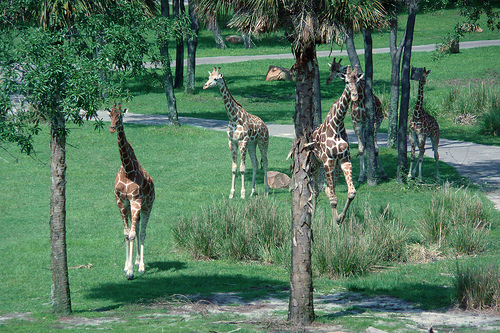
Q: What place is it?
A: It is a park.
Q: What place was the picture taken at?
A: It was taken at the park.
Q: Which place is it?
A: It is a park.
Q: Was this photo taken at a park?
A: Yes, it was taken in a park.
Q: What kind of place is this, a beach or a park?
A: It is a park.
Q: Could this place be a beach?
A: No, it is a park.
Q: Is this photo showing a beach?
A: No, the picture is showing a park.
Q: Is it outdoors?
A: Yes, it is outdoors.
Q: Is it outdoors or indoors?
A: It is outdoors.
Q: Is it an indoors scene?
A: No, it is outdoors.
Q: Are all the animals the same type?
A: Yes, all the animals are giraffes.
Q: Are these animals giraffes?
A: Yes, all the animals are giraffes.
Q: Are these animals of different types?
A: No, all the animals are giraffes.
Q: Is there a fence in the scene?
A: No, there are no fences.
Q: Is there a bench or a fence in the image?
A: No, there are no fences or benches.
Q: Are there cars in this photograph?
A: No, there are no cars.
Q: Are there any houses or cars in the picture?
A: No, there are no cars or houses.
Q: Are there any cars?
A: No, there are no cars.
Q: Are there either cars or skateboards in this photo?
A: No, there are no cars or skateboards.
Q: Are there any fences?
A: No, there are no fences.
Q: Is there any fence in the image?
A: No, there are no fences.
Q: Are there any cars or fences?
A: No, there are no fences or cars.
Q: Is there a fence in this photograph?
A: No, there are no fences.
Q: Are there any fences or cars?
A: No, there are no fences or cars.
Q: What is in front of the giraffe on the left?
A: The tree is in front of the giraffe.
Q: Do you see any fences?
A: No, there are no fences.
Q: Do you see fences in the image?
A: No, there are no fences.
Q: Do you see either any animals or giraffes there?
A: Yes, there is a giraffe.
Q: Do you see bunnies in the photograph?
A: No, there are no bunnies.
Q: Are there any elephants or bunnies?
A: No, there are no bunnies or elephants.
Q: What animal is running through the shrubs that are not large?
A: The giraffe is running through the shrubs.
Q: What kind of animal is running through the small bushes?
A: The animal is a giraffe.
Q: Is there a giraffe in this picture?
A: Yes, there is a giraffe.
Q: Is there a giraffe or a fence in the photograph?
A: Yes, there is a giraffe.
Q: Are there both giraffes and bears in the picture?
A: No, there is a giraffe but no bears.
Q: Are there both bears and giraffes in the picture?
A: No, there is a giraffe but no bears.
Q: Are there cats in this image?
A: No, there are no cats.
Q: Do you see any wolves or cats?
A: No, there are no cats or wolves.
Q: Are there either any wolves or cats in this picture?
A: No, there are no cats or wolves.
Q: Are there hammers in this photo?
A: No, there are no hammers.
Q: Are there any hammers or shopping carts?
A: No, there are no hammers or shopping carts.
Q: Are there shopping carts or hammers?
A: No, there are no hammers or shopping carts.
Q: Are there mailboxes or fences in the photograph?
A: No, there are no fences or mailboxes.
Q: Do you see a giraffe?
A: Yes, there is a giraffe.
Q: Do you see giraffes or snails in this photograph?
A: Yes, there is a giraffe.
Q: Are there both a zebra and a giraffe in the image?
A: No, there is a giraffe but no zebras.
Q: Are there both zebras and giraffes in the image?
A: No, there is a giraffe but no zebras.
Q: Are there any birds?
A: No, there are no birds.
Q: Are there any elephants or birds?
A: No, there are no birds or elephants.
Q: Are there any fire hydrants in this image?
A: No, there are no fire hydrants.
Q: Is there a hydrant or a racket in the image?
A: No, there are no fire hydrants or rackets.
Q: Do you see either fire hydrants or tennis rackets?
A: No, there are no fire hydrants or tennis rackets.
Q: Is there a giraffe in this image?
A: Yes, there is a giraffe.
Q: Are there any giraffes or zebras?
A: Yes, there is a giraffe.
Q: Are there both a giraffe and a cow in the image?
A: No, there is a giraffe but no cows.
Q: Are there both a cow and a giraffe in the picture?
A: No, there is a giraffe but no cows.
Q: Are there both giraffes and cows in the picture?
A: No, there is a giraffe but no cows.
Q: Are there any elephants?
A: No, there are no elephants.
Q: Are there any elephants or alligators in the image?
A: No, there are no elephants or alligators.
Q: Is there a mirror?
A: No, there are no mirrors.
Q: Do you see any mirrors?
A: No, there are no mirrors.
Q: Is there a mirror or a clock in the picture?
A: No, there are no mirrors or clocks.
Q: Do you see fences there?
A: No, there are no fences.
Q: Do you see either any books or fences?
A: No, there are no fences or books.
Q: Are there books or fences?
A: No, there are no fences or books.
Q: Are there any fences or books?
A: No, there are no fences or books.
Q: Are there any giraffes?
A: Yes, there is a giraffe.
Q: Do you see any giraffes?
A: Yes, there is a giraffe.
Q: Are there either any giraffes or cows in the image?
A: Yes, there is a giraffe.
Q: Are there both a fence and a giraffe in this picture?
A: No, there is a giraffe but no fences.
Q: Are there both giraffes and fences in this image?
A: No, there is a giraffe but no fences.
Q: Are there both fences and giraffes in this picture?
A: No, there is a giraffe but no fences.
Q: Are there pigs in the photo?
A: No, there are no pigs.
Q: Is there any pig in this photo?
A: No, there are no pigs.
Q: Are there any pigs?
A: No, there are no pigs.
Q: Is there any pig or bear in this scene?
A: No, there are no pigs or bears.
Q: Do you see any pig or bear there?
A: No, there are no pigs or bears.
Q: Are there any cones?
A: No, there are no cones.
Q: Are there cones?
A: No, there are no cones.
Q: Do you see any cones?
A: No, there are no cones.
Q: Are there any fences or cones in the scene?
A: No, there are no cones or fences.